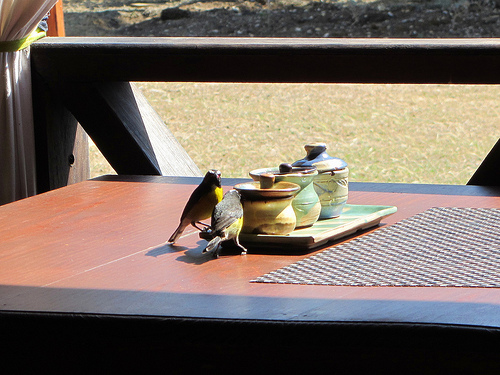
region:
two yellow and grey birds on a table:
[166, 170, 244, 258]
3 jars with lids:
[230, 141, 345, 231]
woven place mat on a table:
[250, 205, 495, 285]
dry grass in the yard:
[165, 85, 495, 135]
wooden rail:
[26, 35, 497, 181]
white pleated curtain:
[0, 0, 60, 201]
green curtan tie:
[0, 31, 43, 51]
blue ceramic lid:
[291, 142, 343, 168]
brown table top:
[0, 170, 496, 328]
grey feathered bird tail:
[168, 222, 189, 244]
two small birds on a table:
[164, 165, 246, 252]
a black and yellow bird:
[166, 166, 223, 246]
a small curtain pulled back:
[0, 0, 58, 207]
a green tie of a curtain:
[1, 28, 51, 56]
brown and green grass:
[125, 78, 497, 185]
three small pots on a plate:
[224, 140, 397, 255]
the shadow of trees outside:
[62, 0, 497, 36]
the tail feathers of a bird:
[198, 223, 225, 262]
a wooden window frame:
[27, 32, 497, 182]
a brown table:
[2, 170, 497, 362]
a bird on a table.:
[166, 163, 238, 254]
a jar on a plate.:
[284, 143, 354, 223]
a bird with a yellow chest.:
[203, 182, 231, 209]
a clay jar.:
[286, 131, 363, 224]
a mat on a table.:
[259, 192, 497, 312]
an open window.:
[118, 75, 498, 190]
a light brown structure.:
[44, 0, 80, 47]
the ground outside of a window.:
[51, 0, 498, 39]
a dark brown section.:
[1, 283, 487, 374]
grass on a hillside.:
[71, 0, 492, 43]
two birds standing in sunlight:
[171, 163, 247, 265]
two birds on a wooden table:
[15, 135, 249, 322]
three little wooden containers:
[237, 140, 352, 237]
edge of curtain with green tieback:
[4, 2, 58, 197]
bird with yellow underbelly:
[214, 184, 248, 263]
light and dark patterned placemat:
[256, 198, 498, 318]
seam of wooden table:
[18, 244, 155, 301]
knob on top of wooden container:
[257, 171, 276, 189]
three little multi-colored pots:
[236, 136, 353, 242]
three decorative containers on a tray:
[237, 137, 402, 251]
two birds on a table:
[150, 159, 247, 271]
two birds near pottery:
[161, 160, 301, 270]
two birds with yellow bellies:
[167, 163, 254, 268]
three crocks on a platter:
[233, 130, 390, 256]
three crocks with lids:
[230, 120, 364, 241]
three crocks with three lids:
[234, 140, 390, 245]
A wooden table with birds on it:
[35, 128, 461, 337]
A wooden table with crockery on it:
[90, 141, 435, 330]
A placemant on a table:
[312, 220, 498, 304]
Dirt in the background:
[86, 4, 463, 36]